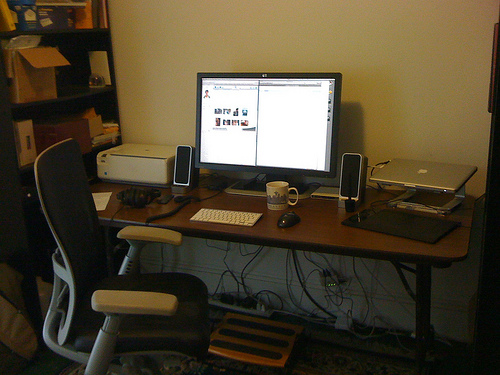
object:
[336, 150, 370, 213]
speaker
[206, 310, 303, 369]
rug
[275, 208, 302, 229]
mouse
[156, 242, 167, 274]
power strip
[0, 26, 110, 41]
shelf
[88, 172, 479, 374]
table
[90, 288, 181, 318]
armrest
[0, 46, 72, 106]
box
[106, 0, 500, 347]
wall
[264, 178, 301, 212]
mug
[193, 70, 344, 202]
monitor